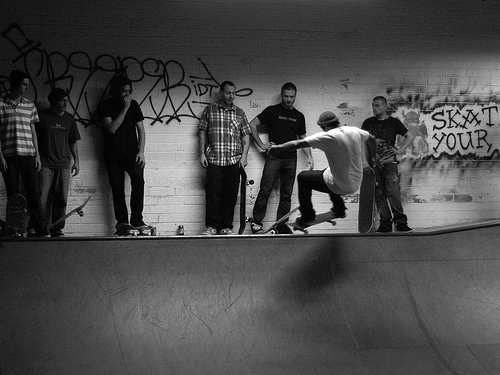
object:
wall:
[2, 2, 498, 238]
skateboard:
[285, 210, 343, 234]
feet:
[296, 214, 317, 225]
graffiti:
[2, 31, 253, 127]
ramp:
[0, 217, 498, 370]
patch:
[457, 326, 497, 370]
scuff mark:
[180, 274, 250, 340]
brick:
[71, 186, 109, 198]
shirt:
[302, 126, 369, 195]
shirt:
[198, 100, 252, 166]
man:
[97, 74, 153, 229]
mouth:
[125, 96, 130, 98]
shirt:
[0, 93, 40, 156]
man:
[198, 81, 252, 235]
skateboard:
[238, 167, 254, 235]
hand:
[388, 146, 400, 156]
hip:
[370, 148, 398, 170]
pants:
[296, 170, 359, 219]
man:
[266, 112, 385, 224]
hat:
[317, 111, 339, 126]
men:
[0, 69, 50, 237]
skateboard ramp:
[0, 214, 497, 372]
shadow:
[249, 225, 360, 323]